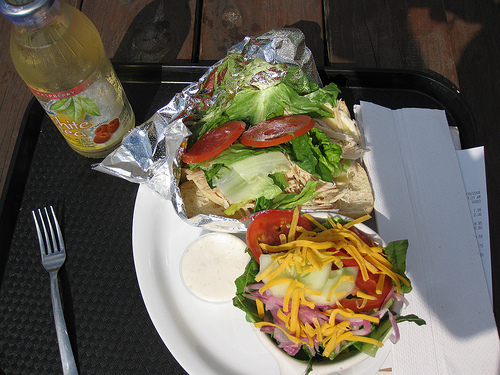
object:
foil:
[88, 27, 321, 232]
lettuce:
[191, 83, 341, 212]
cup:
[177, 232, 252, 303]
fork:
[29, 205, 80, 375]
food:
[180, 60, 399, 362]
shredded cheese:
[335, 310, 379, 325]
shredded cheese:
[299, 285, 316, 309]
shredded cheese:
[342, 213, 372, 230]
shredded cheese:
[304, 250, 335, 273]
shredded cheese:
[338, 308, 354, 319]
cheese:
[272, 326, 290, 344]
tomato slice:
[183, 120, 246, 164]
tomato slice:
[240, 114, 315, 147]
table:
[0, 0, 500, 62]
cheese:
[255, 298, 265, 318]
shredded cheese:
[255, 241, 310, 281]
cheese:
[327, 275, 353, 301]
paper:
[350, 100, 500, 375]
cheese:
[260, 244, 290, 279]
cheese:
[259, 280, 303, 293]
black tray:
[1, 62, 500, 375]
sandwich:
[179, 58, 372, 219]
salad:
[257, 224, 383, 347]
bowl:
[248, 212, 403, 370]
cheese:
[317, 227, 350, 242]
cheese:
[300, 256, 321, 274]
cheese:
[287, 207, 300, 229]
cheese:
[313, 327, 352, 355]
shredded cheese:
[305, 309, 349, 355]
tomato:
[327, 236, 392, 311]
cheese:
[353, 248, 391, 276]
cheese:
[321, 334, 338, 357]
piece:
[287, 206, 299, 242]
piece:
[343, 245, 370, 282]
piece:
[325, 275, 353, 302]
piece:
[258, 251, 332, 297]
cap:
[0, 0, 55, 19]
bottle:
[0, 0, 135, 160]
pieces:
[343, 214, 371, 229]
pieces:
[371, 247, 393, 295]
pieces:
[254, 255, 287, 282]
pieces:
[300, 286, 316, 309]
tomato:
[246, 210, 312, 262]